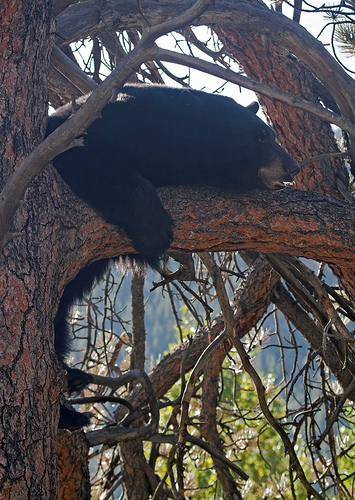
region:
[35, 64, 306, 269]
black bear on a tree branch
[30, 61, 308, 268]
beat holding branch of tree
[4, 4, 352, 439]
tree with a bear in it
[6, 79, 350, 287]
limb of tree with a bear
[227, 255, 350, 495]
tree branches without leaves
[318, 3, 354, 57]
branch with pine needles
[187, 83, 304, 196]
head of bear with mouth open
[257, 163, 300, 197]
mouth of bear with pink tongue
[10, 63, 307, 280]
bear hugging a tree's branch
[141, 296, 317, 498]
tree with green foliage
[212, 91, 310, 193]
head of a bear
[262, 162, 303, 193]
mouth of a bear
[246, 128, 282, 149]
eye of a bear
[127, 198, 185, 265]
paw of a bear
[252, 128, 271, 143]
eye of a bear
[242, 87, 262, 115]
ear of a bear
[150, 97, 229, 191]
neck of a bear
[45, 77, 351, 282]
bear hugging a tree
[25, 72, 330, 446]
bear is on a tree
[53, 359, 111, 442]
feet of a bear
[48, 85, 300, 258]
Black bear resting on a tree limb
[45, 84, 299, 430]
Black bear climbing a dead tree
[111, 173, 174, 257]
Black bear paw resting on a limb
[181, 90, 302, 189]
Black bear's head with open mouth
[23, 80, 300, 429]
Black bear relaxing in a dead pine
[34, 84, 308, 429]
Adult bear climbing in a dead tree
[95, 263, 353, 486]
A tangle a dead branches in a tree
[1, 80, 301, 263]
Tired bear lazing on a limb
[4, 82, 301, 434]
Bear relaxing in a Ponderosa pine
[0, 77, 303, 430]
Black bear hugging a Ponderosa pine.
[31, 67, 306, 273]
the bear is black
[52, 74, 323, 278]
bear is hugging the tree